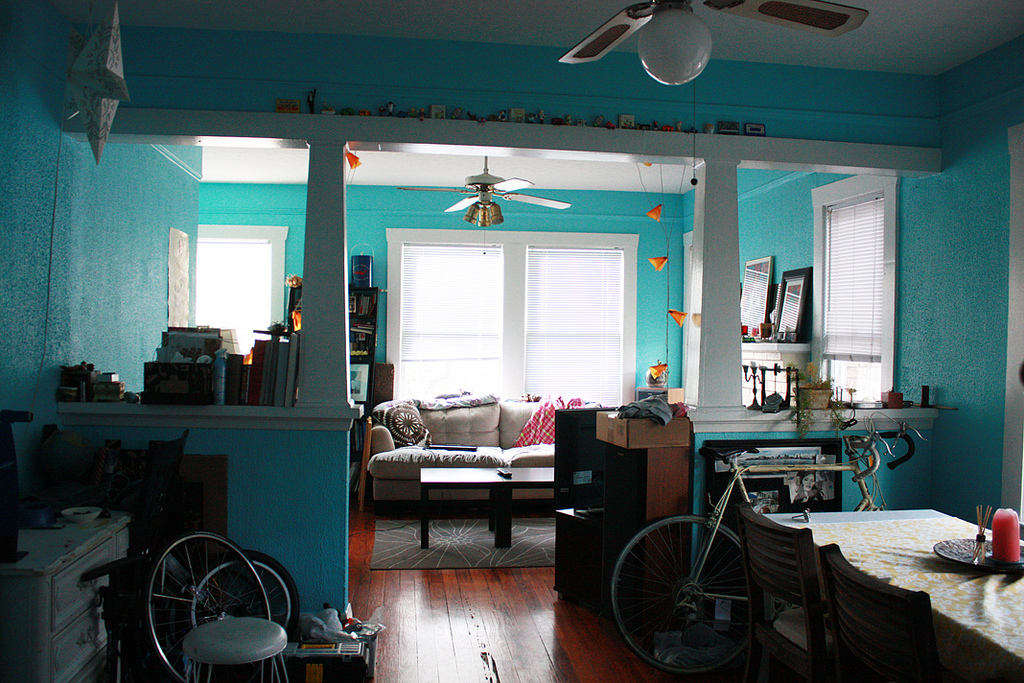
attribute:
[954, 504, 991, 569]
diffuser — reed